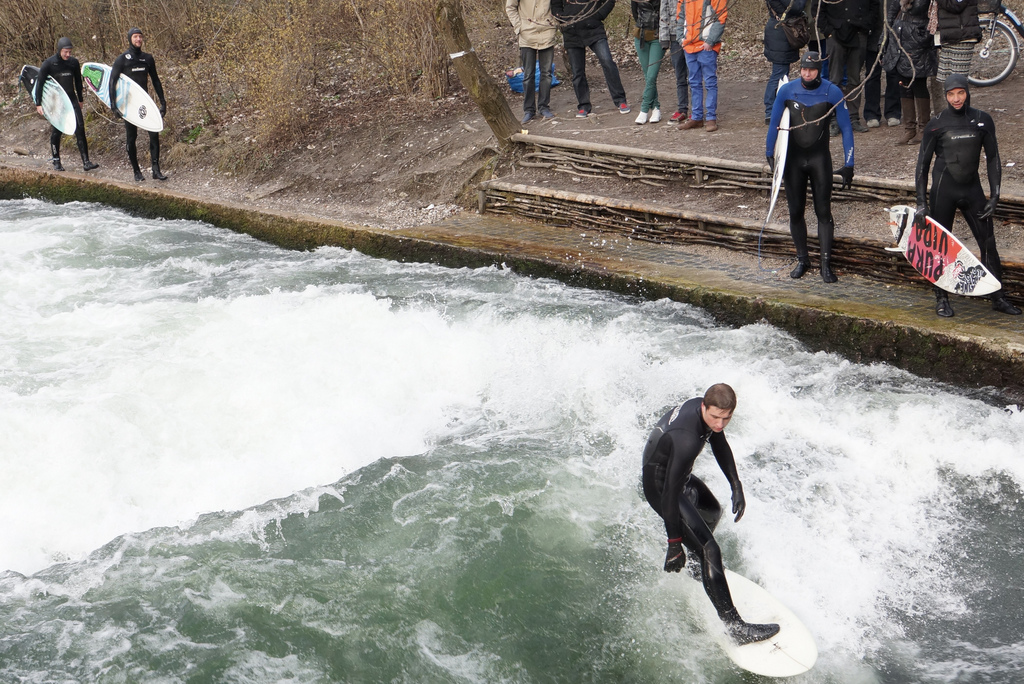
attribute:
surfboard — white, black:
[16, 64, 80, 137]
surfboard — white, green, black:
[78, 62, 171, 136]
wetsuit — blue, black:
[756, 59, 871, 290]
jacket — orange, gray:
[659, 2, 723, 63]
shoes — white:
[624, 35, 672, 124]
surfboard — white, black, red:
[880, 207, 1010, 322]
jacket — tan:
[506, 3, 555, 52]